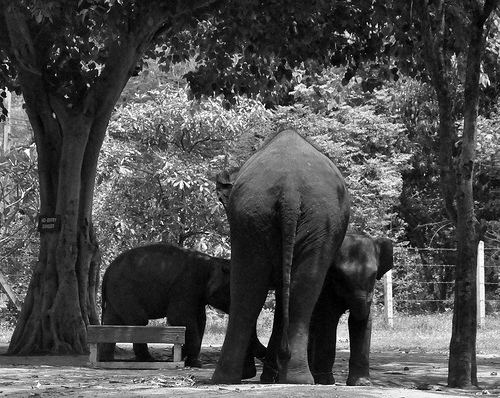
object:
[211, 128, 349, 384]
elephant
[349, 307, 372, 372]
legs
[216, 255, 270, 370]
left leg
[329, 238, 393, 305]
head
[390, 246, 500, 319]
fence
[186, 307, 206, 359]
front legs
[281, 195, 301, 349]
tail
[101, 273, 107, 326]
tail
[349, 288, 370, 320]
trunk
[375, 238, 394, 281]
ear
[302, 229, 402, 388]
elephant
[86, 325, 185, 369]
bar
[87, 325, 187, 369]
bench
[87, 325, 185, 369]
wood post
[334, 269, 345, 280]
eyes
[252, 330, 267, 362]
trunk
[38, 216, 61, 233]
sign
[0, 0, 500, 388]
tree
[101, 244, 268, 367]
elephant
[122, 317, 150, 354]
leg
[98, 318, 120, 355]
leg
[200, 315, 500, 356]
overgrown grass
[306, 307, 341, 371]
leg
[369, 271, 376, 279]
eye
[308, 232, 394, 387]
elephant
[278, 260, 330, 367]
leg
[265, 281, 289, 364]
leg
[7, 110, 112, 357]
tree trunk